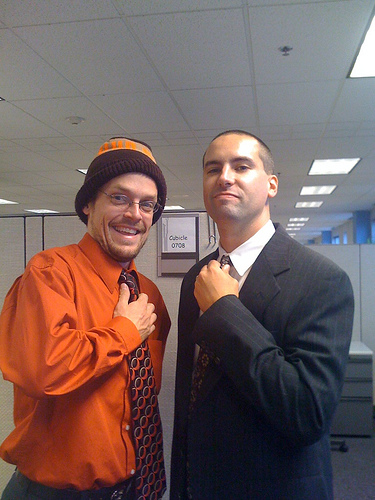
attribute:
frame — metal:
[97, 187, 164, 211]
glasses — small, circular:
[98, 188, 166, 218]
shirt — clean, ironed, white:
[186, 221, 265, 401]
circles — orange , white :
[121, 273, 167, 498]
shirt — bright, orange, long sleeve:
[0, 231, 171, 491]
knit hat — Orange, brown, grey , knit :
[96, 136, 162, 174]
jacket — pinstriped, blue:
[181, 244, 337, 498]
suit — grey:
[173, 222, 354, 494]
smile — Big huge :
[99, 218, 150, 248]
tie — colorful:
[117, 269, 167, 498]